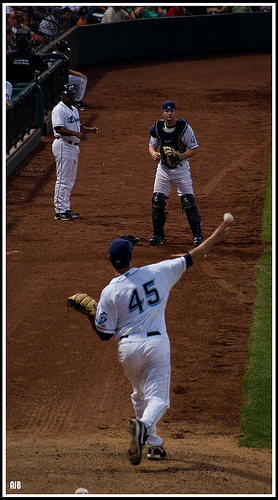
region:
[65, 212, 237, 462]
baseball player warming up before the game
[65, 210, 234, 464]
baseball player throwing the ball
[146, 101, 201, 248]
catcher about to catch the ball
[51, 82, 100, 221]
coach watching the baseball players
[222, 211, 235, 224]
baseball about to be thrown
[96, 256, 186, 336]
white shirt with the number 45 on it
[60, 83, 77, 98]
black helmet on the coach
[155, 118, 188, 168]
protective gear on the catcher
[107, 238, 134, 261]
blue baseball hat on the pitcher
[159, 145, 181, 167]
tan glove on the catcher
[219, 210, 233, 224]
Base ball in mid-air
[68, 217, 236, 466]
baseball player throwing base ball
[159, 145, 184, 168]
Baseball mitts on the right hand of the baseball player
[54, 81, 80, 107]
Baseball player's head wearing helmet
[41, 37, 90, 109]
Baseball player sitting near the wall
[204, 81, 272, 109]
Foot marks on the sand in the baseball field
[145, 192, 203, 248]
Baseball player's knee guard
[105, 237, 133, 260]
Baseball cap on the head of the player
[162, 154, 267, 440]
Foot marks beside the grass in the baseball fieldfield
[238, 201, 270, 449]
Green grass on the base ball field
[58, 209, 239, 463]
baseball player throwing a ball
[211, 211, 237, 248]
baseball being thrown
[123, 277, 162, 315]
number on the back of a white jersey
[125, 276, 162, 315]
fourty five print on the back of jersey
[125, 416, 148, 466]
baseball cleat on a player's foot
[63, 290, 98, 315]
baseball glove on a player's hand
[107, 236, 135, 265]
blue hat on a baseball player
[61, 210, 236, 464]
baseball player pitching a ball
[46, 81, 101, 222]
baseball player standing on a dirt field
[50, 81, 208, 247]
two baseball players on a field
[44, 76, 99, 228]
The man is wearing a helmet.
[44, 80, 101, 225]
The man is wearing a uniform.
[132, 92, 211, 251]
The man is wearing a cap.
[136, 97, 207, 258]
The man is wearing a uniform.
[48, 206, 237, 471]
The man is wearing a uniform.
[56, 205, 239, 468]
The man is wearing a cap.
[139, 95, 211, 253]
The man is wearing a baseball glove.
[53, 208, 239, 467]
The man is holding a baseball glove.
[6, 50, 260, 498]
The ground is covered in dirt.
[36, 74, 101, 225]
The man's helmet is blue and white.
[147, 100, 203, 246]
a baseball catcher on field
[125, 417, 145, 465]
a black and white athletic shoe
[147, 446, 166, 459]
a black and white athletic shoe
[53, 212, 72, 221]
a black and white athletic shoe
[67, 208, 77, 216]
a black and white athletic shoe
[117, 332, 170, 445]
a pair of white pants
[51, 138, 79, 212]
a pair of white pants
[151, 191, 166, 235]
black shin guards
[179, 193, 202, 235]
black shin guards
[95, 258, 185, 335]
a white baseball jersey number45